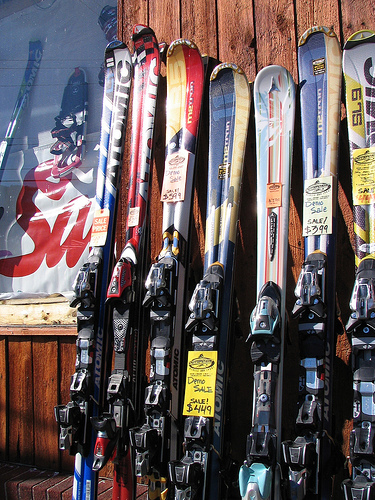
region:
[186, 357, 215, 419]
price tag on the skis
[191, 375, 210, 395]
Demo Sale written on the price tag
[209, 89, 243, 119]
11 is on the ski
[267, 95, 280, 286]
red stripes on the ski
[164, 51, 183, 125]
yellow on the ski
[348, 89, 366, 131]
675 written on the ski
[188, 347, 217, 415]
price tag is yellow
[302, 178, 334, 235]
price tag is white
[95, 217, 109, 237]
price tag says SALE PRICE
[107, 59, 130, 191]
ATOMIC written on the skis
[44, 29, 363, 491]
skis propped against wall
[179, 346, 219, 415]
black lettering on yellow background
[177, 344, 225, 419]
yellow tag on ski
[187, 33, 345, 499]
two matching blue and white skis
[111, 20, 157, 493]
red and white ski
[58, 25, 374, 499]
seven skis lined up together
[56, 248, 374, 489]
boot clips on skis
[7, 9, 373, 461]
wood wall behind skis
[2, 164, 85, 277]
red lettering on white background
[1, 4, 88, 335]
display window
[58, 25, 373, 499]
skis for sale outside of store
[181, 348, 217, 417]
yellow and black sale sign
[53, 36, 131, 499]
blue and white ATOMIC skies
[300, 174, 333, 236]
black and white sign on ski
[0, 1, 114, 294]
window of ski shop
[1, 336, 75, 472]
wooden wall of ski store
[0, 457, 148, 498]
brick against wooden wall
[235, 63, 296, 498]
pink, light blue, white and peach ski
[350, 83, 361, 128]
675 in black on yellow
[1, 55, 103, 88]
utility lines reflected in window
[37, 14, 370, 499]
skies lined up on the wall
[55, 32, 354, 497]
skies lined on a wall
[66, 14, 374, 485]
a line of skies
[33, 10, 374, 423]
skies next to a window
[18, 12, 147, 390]
a window with a display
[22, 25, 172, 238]
snow shoes on display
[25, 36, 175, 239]
snow shoes in the window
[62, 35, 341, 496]
skies for sale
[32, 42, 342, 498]
snow skies on sale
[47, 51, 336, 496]
snow skies leaning on a wall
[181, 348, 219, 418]
yellow price tag on ski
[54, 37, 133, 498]
tall blue ski standing up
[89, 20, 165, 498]
red ski standing next to blue ski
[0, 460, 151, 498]
brick trim at bottom of building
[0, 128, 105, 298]
red and white sign in window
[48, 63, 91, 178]
snowshoe hanging in window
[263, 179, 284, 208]
small orange price tag on ski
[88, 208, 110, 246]
white and red price tag on ski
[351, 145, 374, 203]
yellow price tag on yellow and black ski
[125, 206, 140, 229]
small white price tag on red ski